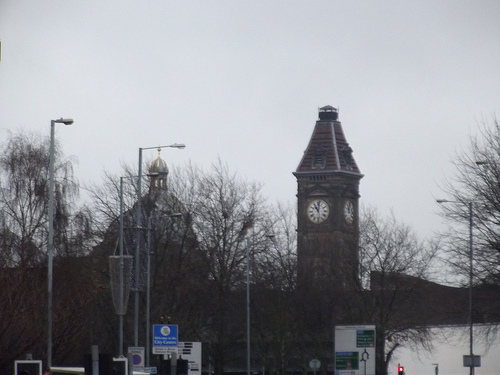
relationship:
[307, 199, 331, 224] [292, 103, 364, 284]
clock on tower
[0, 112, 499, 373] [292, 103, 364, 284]
trees around tower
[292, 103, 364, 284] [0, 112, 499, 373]
tower amongst trees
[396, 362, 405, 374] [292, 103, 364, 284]
traffic light below tower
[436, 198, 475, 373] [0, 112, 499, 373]
lamp post amongst trees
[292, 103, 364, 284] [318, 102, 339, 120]
tower has a roof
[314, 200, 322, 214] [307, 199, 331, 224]
hands on clock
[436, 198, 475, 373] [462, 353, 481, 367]
lamp post has a sign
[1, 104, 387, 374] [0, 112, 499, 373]
building behind trees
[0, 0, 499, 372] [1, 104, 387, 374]
sky above building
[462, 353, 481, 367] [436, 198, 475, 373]
sign on lamp post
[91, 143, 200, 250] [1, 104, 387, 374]
dome on building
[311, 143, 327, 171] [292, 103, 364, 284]
window on tower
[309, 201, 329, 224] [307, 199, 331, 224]
roman numerals on clock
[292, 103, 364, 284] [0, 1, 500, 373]
tower in city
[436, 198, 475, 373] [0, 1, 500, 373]
lamp post in city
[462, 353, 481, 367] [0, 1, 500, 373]
sign in city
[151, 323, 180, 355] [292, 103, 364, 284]
sign near tower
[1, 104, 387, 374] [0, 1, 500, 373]
building in city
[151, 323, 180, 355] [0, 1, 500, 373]
sign in city